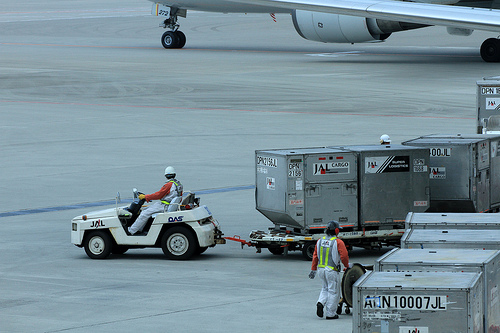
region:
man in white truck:
[60, 157, 231, 260]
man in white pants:
[303, 214, 348, 321]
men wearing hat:
[113, 158, 187, 237]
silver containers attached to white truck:
[57, 140, 438, 263]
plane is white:
[152, 0, 495, 69]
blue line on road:
[9, 0, 489, 327]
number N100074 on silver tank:
[345, 202, 495, 327]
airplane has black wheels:
[140, 0, 494, 67]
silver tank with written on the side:
[245, 135, 441, 227]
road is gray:
[8, 8, 490, 325]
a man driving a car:
[97, 145, 222, 275]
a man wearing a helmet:
[161, 153, 188, 190]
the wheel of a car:
[66, 230, 121, 261]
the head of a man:
[156, 162, 181, 187]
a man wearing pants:
[307, 229, 375, 320]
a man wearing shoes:
[293, 205, 372, 322]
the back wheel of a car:
[154, 208, 237, 259]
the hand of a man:
[296, 260, 330, 292]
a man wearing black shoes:
[303, 288, 350, 330]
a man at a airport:
[262, 202, 439, 317]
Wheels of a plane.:
[153, 23, 192, 56]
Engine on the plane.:
[288, 0, 384, 46]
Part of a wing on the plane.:
[378, 1, 487, 34]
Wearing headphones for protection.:
[319, 218, 354, 239]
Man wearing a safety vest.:
[312, 236, 347, 272]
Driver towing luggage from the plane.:
[128, 160, 191, 245]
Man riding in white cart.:
[68, 157, 220, 269]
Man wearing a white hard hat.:
[158, 160, 187, 187]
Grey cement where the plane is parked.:
[157, 43, 292, 141]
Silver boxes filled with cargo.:
[252, 120, 436, 229]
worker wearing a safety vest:
[313, 229, 341, 265]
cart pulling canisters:
[73, 199, 228, 255]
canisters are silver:
[259, 137, 498, 233]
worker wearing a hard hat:
[162, 160, 183, 182]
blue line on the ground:
[13, 166, 268, 226]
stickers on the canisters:
[355, 294, 444, 330]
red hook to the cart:
[215, 221, 277, 266]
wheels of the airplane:
[150, 24, 201, 61]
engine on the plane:
[270, 1, 390, 79]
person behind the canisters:
[365, 115, 420, 160]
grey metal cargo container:
[404, 199, 489, 237]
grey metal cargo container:
[399, 217, 490, 250]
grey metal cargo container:
[370, 226, 496, 290]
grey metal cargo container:
[350, 262, 493, 331]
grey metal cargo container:
[467, 63, 498, 128]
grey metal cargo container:
[411, 118, 496, 194]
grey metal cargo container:
[251, 132, 444, 245]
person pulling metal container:
[40, 128, 445, 250]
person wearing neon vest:
[154, 174, 195, 222]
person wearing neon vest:
[308, 228, 364, 298]